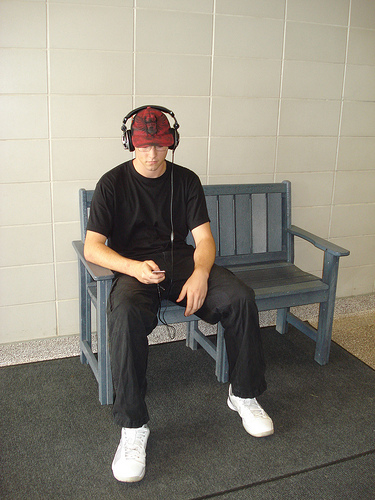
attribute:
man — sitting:
[80, 104, 276, 484]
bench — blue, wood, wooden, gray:
[73, 180, 350, 408]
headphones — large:
[120, 104, 184, 149]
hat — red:
[131, 107, 176, 147]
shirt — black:
[84, 156, 214, 252]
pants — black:
[108, 250, 268, 425]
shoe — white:
[108, 421, 155, 485]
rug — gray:
[5, 320, 375, 499]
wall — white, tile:
[2, 0, 375, 342]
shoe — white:
[223, 382, 279, 442]